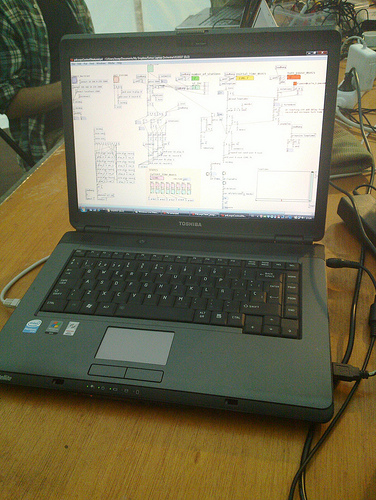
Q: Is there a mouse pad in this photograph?
A: Yes, there is a mouse pad.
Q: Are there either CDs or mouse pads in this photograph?
A: Yes, there is a mouse pad.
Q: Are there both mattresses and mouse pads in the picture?
A: No, there is a mouse pad but no mattresses.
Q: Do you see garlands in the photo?
A: No, there are no garlands.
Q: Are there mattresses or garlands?
A: No, there are no garlands or mattresses.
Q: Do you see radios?
A: No, there are no radios.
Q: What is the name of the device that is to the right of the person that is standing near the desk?
A: The device is a screen.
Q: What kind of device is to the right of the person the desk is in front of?
A: The device is a screen.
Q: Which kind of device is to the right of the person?
A: The device is a screen.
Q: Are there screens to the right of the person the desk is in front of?
A: Yes, there is a screen to the right of the person.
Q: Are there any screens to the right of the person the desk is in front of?
A: Yes, there is a screen to the right of the person.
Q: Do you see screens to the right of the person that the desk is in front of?
A: Yes, there is a screen to the right of the person.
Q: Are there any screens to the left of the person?
A: No, the screen is to the right of the person.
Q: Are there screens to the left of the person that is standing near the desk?
A: No, the screen is to the right of the person.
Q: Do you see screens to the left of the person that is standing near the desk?
A: No, the screen is to the right of the person.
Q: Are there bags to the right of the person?
A: No, there is a screen to the right of the person.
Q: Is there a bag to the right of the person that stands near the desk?
A: No, there is a screen to the right of the person.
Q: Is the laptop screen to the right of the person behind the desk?
A: Yes, the screen is to the right of the person.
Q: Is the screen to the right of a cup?
A: No, the screen is to the right of the person.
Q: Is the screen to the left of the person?
A: No, the screen is to the right of the person.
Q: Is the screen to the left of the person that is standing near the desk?
A: No, the screen is to the right of the person.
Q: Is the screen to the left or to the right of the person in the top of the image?
A: The screen is to the right of the person.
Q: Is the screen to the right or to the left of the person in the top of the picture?
A: The screen is to the right of the person.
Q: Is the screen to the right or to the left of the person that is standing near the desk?
A: The screen is to the right of the person.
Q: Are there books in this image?
A: No, there are no books.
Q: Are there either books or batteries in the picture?
A: No, there are no books or batteries.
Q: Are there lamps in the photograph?
A: No, there are no lamps.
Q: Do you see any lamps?
A: No, there are no lamps.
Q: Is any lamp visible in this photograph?
A: No, there are no lamps.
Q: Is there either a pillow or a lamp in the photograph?
A: No, there are no lamps or pillows.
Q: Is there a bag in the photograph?
A: No, there are no bags.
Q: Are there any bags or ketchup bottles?
A: No, there are no bags or ketchup bottles.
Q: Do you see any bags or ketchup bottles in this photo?
A: No, there are no bags or ketchup bottles.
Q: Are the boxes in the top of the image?
A: Yes, the boxes are in the top of the image.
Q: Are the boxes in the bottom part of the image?
A: No, the boxes are in the top of the image.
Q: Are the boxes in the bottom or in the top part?
A: The boxes are in the top of the image.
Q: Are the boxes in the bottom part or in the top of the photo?
A: The boxes are in the top of the image.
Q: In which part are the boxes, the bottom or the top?
A: The boxes are in the top of the image.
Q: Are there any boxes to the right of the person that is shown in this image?
A: Yes, there are boxes to the right of the person.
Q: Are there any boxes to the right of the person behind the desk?
A: Yes, there are boxes to the right of the person.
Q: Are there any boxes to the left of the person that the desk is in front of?
A: No, the boxes are to the right of the person.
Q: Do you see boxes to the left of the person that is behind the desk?
A: No, the boxes are to the right of the person.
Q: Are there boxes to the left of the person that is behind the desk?
A: No, the boxes are to the right of the person.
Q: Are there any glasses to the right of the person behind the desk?
A: No, there are boxes to the right of the person.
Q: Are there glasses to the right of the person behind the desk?
A: No, there are boxes to the right of the person.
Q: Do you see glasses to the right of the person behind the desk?
A: No, there are boxes to the right of the person.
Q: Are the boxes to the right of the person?
A: Yes, the boxes are to the right of the person.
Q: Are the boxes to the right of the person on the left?
A: Yes, the boxes are to the right of the person.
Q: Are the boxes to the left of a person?
A: No, the boxes are to the right of a person.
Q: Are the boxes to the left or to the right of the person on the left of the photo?
A: The boxes are to the right of the person.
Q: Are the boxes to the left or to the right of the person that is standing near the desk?
A: The boxes are to the right of the person.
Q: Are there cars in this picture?
A: No, there are no cars.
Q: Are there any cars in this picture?
A: No, there are no cars.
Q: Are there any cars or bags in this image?
A: No, there are no cars or bags.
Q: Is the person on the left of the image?
A: Yes, the person is on the left of the image.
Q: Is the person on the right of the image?
A: No, the person is on the left of the image.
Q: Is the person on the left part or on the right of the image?
A: The person is on the left of the image.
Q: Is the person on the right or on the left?
A: The person is on the left of the image.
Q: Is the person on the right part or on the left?
A: The person is on the left of the image.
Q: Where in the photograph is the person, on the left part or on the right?
A: The person is on the left of the image.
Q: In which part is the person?
A: The person is on the left of the image.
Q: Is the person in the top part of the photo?
A: Yes, the person is in the top of the image.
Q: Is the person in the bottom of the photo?
A: No, the person is in the top of the image.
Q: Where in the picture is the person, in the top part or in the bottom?
A: The person is in the top of the image.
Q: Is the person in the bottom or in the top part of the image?
A: The person is in the top of the image.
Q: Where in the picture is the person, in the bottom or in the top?
A: The person is in the top of the image.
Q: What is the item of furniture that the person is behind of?
A: The piece of furniture is a desk.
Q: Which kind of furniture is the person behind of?
A: The person is behind the desk.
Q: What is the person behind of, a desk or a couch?
A: The person is behind a desk.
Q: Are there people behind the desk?
A: Yes, there is a person behind the desk.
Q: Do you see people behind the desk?
A: Yes, there is a person behind the desk.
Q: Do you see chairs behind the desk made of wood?
A: No, there is a person behind the desk.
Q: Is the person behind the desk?
A: Yes, the person is behind the desk.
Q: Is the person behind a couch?
A: No, the person is behind the desk.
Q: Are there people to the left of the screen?
A: Yes, there is a person to the left of the screen.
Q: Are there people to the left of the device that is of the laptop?
A: Yes, there is a person to the left of the screen.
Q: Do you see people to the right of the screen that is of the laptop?
A: No, the person is to the left of the screen.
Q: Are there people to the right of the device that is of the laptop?
A: No, the person is to the left of the screen.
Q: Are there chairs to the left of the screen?
A: No, there is a person to the left of the screen.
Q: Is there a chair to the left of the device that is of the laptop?
A: No, there is a person to the left of the screen.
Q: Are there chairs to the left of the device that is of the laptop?
A: No, there is a person to the left of the screen.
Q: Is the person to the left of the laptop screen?
A: Yes, the person is to the left of the screen.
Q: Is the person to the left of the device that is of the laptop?
A: Yes, the person is to the left of the screen.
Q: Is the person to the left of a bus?
A: No, the person is to the left of the screen.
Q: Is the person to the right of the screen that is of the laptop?
A: No, the person is to the left of the screen.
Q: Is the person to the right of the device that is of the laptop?
A: No, the person is to the left of the screen.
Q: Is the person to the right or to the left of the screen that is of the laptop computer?
A: The person is to the left of the screen.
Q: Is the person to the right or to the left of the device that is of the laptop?
A: The person is to the left of the screen.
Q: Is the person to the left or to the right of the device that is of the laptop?
A: The person is to the left of the screen.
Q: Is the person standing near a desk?
A: Yes, the person is standing near a desk.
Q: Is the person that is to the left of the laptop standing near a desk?
A: Yes, the person is standing near a desk.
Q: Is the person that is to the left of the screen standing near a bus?
A: No, the person is standing near a desk.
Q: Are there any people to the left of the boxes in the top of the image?
A: Yes, there is a person to the left of the boxes.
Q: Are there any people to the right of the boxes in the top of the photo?
A: No, the person is to the left of the boxes.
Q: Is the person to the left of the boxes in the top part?
A: Yes, the person is to the left of the boxes.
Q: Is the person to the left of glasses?
A: No, the person is to the left of the boxes.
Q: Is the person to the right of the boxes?
A: No, the person is to the left of the boxes.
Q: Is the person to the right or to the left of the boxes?
A: The person is to the left of the boxes.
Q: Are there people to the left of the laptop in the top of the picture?
A: Yes, there is a person to the left of the laptop.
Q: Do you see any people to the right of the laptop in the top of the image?
A: No, the person is to the left of the laptop computer.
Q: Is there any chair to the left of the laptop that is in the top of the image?
A: No, there is a person to the left of the laptop.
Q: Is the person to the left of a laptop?
A: Yes, the person is to the left of a laptop.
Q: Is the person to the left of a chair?
A: No, the person is to the left of a laptop.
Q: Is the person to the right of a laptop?
A: No, the person is to the left of a laptop.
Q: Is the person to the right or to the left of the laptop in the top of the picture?
A: The person is to the left of the laptop.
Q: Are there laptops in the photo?
A: Yes, there is a laptop.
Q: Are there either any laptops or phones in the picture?
A: Yes, there is a laptop.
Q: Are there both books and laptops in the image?
A: No, there is a laptop but no books.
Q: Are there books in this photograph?
A: No, there are no books.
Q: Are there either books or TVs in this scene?
A: No, there are no books or tvs.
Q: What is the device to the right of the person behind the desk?
A: The device is a laptop.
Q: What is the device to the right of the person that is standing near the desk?
A: The device is a laptop.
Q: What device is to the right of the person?
A: The device is a laptop.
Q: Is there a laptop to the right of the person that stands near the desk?
A: Yes, there is a laptop to the right of the person.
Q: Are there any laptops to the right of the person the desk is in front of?
A: Yes, there is a laptop to the right of the person.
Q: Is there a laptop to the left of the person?
A: No, the laptop is to the right of the person.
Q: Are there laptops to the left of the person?
A: No, the laptop is to the right of the person.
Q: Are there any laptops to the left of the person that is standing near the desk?
A: No, the laptop is to the right of the person.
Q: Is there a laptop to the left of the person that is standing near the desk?
A: No, the laptop is to the right of the person.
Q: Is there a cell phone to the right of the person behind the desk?
A: No, there is a laptop to the right of the person.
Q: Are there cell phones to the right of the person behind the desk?
A: No, there is a laptop to the right of the person.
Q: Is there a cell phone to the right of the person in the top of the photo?
A: No, there is a laptop to the right of the person.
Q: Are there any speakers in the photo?
A: No, there are no speakers.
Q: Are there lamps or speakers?
A: No, there are no speakers or lamps.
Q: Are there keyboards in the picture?
A: Yes, there is a keyboard.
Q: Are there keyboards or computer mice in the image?
A: Yes, there is a keyboard.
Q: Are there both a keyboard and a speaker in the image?
A: No, there is a keyboard but no speakers.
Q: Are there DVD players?
A: No, there are no DVD players.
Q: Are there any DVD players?
A: No, there are no DVD players.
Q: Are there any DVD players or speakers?
A: No, there are no DVD players or speakers.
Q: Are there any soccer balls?
A: No, there are no soccer balls.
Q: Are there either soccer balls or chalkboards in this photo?
A: No, there are no soccer balls or chalkboards.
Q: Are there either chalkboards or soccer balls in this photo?
A: No, there are no soccer balls or chalkboards.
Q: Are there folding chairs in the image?
A: No, there are no folding chairs.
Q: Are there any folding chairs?
A: No, there are no folding chairs.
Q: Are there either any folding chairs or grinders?
A: No, there are no folding chairs or grinders.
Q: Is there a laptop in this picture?
A: Yes, there is a laptop.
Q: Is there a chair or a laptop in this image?
A: Yes, there is a laptop.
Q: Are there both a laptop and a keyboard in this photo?
A: Yes, there are both a laptop and a keyboard.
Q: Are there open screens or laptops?
A: Yes, there is an open laptop.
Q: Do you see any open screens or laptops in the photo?
A: Yes, there is an open laptop.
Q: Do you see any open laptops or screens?
A: Yes, there is an open laptop.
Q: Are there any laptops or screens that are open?
A: Yes, the laptop is open.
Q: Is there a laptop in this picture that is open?
A: Yes, there is a laptop that is open.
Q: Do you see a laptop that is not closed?
A: Yes, there is a open laptop.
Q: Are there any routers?
A: No, there are no routers.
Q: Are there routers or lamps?
A: No, there are no routers or lamps.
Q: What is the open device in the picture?
A: The device is a laptop.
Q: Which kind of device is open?
A: The device is a laptop.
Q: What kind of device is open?
A: The device is a laptop.